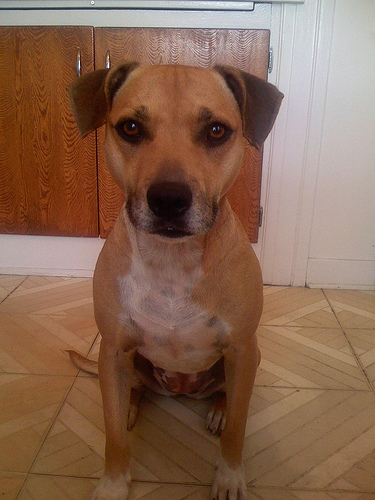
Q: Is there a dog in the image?
A: Yes, there is a dog.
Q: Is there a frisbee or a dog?
A: Yes, there is a dog.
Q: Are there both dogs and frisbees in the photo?
A: No, there is a dog but no frisbees.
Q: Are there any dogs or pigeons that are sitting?
A: Yes, the dog is sitting.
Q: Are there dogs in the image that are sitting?
A: Yes, there is a dog that is sitting.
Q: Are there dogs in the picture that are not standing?
A: Yes, there is a dog that is sitting.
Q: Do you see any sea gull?
A: No, there are no seagulls.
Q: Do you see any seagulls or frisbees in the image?
A: No, there are no seagulls or frisbees.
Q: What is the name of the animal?
A: The animal is a dog.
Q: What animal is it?
A: The animal is a dog.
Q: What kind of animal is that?
A: That is a dog.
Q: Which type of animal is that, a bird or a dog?
A: That is a dog.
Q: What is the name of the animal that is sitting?
A: The animal is a dog.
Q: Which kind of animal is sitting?
A: The animal is a dog.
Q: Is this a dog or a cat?
A: This is a dog.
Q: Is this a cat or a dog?
A: This is a dog.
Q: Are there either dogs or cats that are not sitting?
A: No, there is a dog but it is sitting.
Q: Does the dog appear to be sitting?
A: Yes, the dog is sitting.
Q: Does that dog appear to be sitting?
A: Yes, the dog is sitting.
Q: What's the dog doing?
A: The dog is sitting.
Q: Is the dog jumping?
A: No, the dog is sitting.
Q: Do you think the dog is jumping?
A: No, the dog is sitting.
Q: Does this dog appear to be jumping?
A: No, the dog is sitting.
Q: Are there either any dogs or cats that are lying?
A: No, there is a dog but it is sitting.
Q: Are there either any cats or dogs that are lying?
A: No, there is a dog but it is sitting.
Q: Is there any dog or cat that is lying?
A: No, there is a dog but it is sitting.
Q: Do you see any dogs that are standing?
A: No, there is a dog but it is sitting.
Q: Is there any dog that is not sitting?
A: No, there is a dog but it is sitting.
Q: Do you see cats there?
A: No, there are no cats.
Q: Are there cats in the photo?
A: No, there are no cats.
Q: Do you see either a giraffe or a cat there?
A: No, there are no cats or giraffes.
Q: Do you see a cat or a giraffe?
A: No, there are no cats or giraffes.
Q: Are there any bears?
A: No, there are no bears.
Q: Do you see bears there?
A: No, there are no bears.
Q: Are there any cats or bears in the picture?
A: No, there are no bears or cats.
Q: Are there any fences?
A: No, there are no fences.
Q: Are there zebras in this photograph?
A: No, there are no zebras.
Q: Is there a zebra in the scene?
A: No, there are no zebras.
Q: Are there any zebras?
A: No, there are no zebras.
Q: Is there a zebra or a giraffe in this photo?
A: No, there are no zebras or giraffes.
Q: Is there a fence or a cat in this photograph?
A: No, there are no cats or fences.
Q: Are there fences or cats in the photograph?
A: No, there are no cats or fences.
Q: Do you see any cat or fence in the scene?
A: No, there are no cats or fences.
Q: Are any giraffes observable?
A: No, there are no giraffes.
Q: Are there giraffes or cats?
A: No, there are no giraffes or cats.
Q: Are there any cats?
A: No, there are no cats.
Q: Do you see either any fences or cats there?
A: No, there are no cats or fences.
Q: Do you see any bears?
A: No, there are no bears.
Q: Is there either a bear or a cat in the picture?
A: No, there are no bears or cats.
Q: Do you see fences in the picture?
A: No, there are no fences.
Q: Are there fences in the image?
A: No, there are no fences.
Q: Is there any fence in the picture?
A: No, there are no fences.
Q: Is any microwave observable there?
A: No, there are no microwaves.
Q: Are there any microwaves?
A: No, there are no microwaves.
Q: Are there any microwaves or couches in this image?
A: No, there are no microwaves or couches.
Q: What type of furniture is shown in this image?
A: The furniture is a cupboard.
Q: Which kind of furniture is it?
A: The piece of furniture is a cupboard.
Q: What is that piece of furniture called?
A: This is a cupboard.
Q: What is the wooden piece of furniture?
A: The piece of furniture is a cupboard.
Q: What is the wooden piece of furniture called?
A: The piece of furniture is a cupboard.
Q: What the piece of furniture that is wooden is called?
A: The piece of furniture is a cupboard.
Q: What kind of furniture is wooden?
A: The furniture is a cupboard.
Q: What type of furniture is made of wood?
A: The furniture is a cupboard.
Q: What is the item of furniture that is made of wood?
A: The piece of furniture is a cupboard.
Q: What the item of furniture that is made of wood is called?
A: The piece of furniture is a cupboard.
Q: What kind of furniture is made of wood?
A: The furniture is a cupboard.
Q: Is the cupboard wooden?
A: Yes, the cupboard is wooden.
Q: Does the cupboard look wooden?
A: Yes, the cupboard is wooden.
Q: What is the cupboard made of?
A: The cupboard is made of wood.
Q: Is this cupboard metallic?
A: No, the cupboard is wooden.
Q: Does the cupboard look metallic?
A: No, the cupboard is wooden.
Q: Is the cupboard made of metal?
A: No, the cupboard is made of wood.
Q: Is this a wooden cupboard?
A: Yes, this is a wooden cupboard.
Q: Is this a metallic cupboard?
A: No, this is a wooden cupboard.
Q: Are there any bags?
A: No, there are no bags.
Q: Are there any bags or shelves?
A: No, there are no bags or shelves.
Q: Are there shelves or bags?
A: No, there are no bags or shelves.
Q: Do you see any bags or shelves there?
A: No, there are no bags or shelves.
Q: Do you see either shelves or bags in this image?
A: No, there are no bags or shelves.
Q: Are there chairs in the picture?
A: No, there are no chairs.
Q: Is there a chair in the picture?
A: No, there are no chairs.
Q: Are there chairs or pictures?
A: No, there are no chairs or pictures.